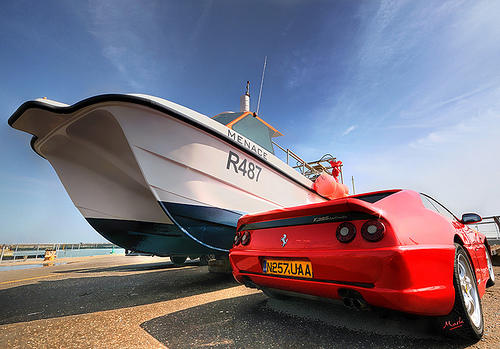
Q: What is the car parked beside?
A: A boat.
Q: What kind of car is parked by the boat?
A: Ferrari.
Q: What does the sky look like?
A: Blue with wispy white clouds.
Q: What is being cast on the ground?
A: Shadows.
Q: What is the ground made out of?
A: Brown asphalt.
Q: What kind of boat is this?
A: A yacht.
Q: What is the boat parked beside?
A: A red car.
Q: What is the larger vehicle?
A: Boat.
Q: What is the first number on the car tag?
A: N.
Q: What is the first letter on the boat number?
A: R.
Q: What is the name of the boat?
A: Menace.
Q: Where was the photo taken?
A: Dock.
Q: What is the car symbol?
A: Horse.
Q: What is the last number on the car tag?
A: A.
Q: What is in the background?
A: Water.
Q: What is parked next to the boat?
A: A car.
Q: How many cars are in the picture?
A: One.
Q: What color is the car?
A: Red.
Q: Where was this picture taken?
A: A dock.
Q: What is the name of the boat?
A: Menace.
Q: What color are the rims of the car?
A: Silver.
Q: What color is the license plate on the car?
A: Yellow.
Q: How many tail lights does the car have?
A: Four.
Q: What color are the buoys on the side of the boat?
A: Orange.